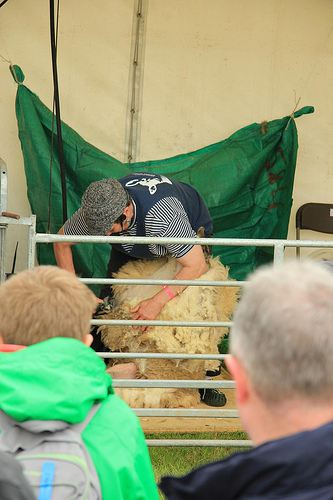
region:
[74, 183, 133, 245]
head of a person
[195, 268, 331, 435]
head of a person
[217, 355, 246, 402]
ear of a person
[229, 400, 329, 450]
neck of a person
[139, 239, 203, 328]
arm of a person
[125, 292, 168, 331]
hand of a person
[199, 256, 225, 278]
elbow of a person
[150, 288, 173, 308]
wrist of a person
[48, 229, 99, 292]
arm of a person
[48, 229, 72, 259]
elbow of a person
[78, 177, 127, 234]
a gray wool cap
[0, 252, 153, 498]
a young boy wearing a bright green jacket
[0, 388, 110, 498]
a light gray backpack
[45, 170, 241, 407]
a woman behind a fence handling a large animal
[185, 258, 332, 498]
a man with gray hair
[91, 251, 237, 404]
some large furry animal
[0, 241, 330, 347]
a silver metal fence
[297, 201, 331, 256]
a black folding chair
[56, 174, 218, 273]
a woman in a black striped shirt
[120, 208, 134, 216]
the woman's left ear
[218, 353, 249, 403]
the man's left ear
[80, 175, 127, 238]
gray hat on woman's head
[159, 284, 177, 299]
pink watch on woman's wrist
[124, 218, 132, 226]
earring hanging from woman's ear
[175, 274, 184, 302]
bracelet on the woman's wrist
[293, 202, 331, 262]
black chair on ground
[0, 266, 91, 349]
the boy's blonde hair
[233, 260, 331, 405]
the man's gray hair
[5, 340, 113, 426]
green hoody on boy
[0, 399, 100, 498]
a gray backpack on the boy's back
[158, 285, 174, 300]
a pink bracelet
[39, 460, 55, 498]
blue stripe on the bag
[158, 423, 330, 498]
blue collar on the man's jacket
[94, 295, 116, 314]
a clippers in the man's hand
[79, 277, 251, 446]
metal fence rails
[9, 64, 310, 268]
a green tarp hanging up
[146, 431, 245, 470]
grass under the fence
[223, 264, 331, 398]
the man has gray hair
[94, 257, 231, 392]
the fur is being cut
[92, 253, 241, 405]
very woolly sheep on its back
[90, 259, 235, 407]
a very woolly sheep being sheared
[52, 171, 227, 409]
a man shearing a very woolly sheep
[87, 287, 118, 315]
sheep shears shearing a sheep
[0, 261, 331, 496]
people watching a sheep being sheared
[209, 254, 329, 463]
man watching a sheep being sheared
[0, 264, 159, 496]
boy watching a sheep being sheared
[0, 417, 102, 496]
a gray backpack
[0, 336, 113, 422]
a green hood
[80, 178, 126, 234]
a gray hat